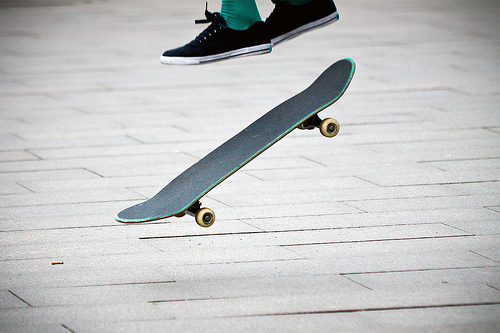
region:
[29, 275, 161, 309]
stone tile on floor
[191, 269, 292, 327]
stone tile on floor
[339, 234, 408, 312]
stone tile on floor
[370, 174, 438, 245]
stone tile on floor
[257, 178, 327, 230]
stone tile on floor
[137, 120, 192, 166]
stone tile on floor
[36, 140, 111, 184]
stone tile on floor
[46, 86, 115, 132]
stone tile on floor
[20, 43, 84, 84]
stone tile on floor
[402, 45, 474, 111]
stone tile on floor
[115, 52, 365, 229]
a skateboard popped in the air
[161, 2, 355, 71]
feet jumped in the air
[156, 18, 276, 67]
black and white skateboard shoes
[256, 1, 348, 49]
black and white skateboard shoes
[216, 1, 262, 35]
green socks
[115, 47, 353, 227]
black skateboard grip tape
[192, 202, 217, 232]
a white skateboard wheel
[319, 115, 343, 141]
a white skateboard wheel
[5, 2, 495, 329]
brick flooring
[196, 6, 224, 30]
black shoe laces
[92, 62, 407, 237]
Skateboard in the air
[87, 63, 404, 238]
Black and green skateboard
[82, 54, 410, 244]
Black and green skateboard in the air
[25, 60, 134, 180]
Brick ground surface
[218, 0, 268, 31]
Green sock of a person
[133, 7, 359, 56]
A person's shoes in the air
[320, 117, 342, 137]
Skateboard wheel in the air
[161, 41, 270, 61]
Sole of a shoe in the air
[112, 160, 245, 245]
Front part of a skateboard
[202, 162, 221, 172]
Black surface of a skateboard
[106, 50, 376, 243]
skateboard jumping above sidewalk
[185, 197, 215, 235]
front wheels of a skateboard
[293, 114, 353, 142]
back wheels of a skateboard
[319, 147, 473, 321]
concrete brick ground under skateboard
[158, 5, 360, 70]
sneakers of a skateboarder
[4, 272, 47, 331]
shadow on the ground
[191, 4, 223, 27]
laces on a sneaker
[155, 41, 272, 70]
white sole of a sneaker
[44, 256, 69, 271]
cigarette butt on the ground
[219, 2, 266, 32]
green sock on a skateboarder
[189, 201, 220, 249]
the front skateboard wheel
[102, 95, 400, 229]
the skateboard in the picture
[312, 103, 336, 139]
the back wheel of skateboard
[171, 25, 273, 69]
the left shoe of the skateboarder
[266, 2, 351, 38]
the right shoe of the skateboarder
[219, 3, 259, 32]
the green socks of the skateboarder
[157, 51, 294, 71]
the white sole of the sneaker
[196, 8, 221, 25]
the shoelaces of the front shoe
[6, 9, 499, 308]
the bricks on the ground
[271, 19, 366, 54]
the back sole of the shoe